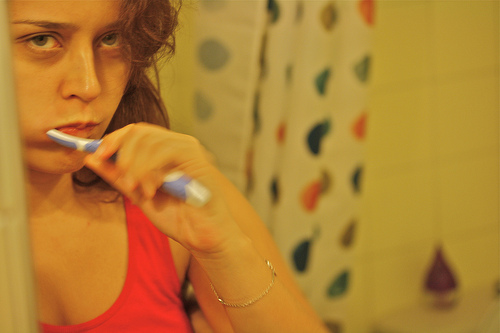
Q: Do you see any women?
A: Yes, there is a woman.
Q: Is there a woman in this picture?
A: Yes, there is a woman.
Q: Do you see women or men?
A: Yes, there is a woman.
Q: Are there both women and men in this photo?
A: No, there is a woman but no men.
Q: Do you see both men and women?
A: No, there is a woman but no men.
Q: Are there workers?
A: No, there are no workers.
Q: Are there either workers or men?
A: No, there are no workers or men.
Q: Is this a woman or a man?
A: This is a woman.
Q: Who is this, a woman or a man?
A: This is a woman.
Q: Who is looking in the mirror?
A: The woman is looking in the mirror.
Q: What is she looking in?
A: The woman is looking in the mirror.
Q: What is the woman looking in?
A: The woman is looking in the mirror.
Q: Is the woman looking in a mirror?
A: Yes, the woman is looking in a mirror.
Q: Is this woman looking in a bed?
A: No, the woman is looking in a mirror.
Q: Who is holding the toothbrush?
A: The woman is holding the toothbrush.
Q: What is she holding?
A: The woman is holding the toothbrush.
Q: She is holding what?
A: The woman is holding the toothbrush.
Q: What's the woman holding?
A: The woman is holding the toothbrush.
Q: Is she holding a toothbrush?
A: Yes, the woman is holding a toothbrush.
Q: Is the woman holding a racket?
A: No, the woman is holding a toothbrush.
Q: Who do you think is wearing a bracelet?
A: The woman is wearing a bracelet.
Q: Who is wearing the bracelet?
A: The woman is wearing a bracelet.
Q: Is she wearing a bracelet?
A: Yes, the woman is wearing a bracelet.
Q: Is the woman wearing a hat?
A: No, the woman is wearing a bracelet.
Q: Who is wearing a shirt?
A: The woman is wearing a shirt.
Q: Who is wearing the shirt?
A: The woman is wearing a shirt.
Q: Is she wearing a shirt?
A: Yes, the woman is wearing a shirt.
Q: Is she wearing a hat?
A: No, the woman is wearing a shirt.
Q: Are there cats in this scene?
A: No, there are no cats.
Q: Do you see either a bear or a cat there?
A: No, there are no cats or bears.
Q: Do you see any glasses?
A: No, there are no glasses.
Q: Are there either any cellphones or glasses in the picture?
A: No, there are no glasses or cellphones.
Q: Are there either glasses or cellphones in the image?
A: No, there are no glasses or cellphones.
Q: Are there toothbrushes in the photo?
A: Yes, there is a toothbrush.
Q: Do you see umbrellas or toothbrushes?
A: Yes, there is a toothbrush.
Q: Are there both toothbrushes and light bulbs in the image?
A: No, there is a toothbrush but no light bulbs.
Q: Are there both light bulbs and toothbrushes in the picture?
A: No, there is a toothbrush but no light bulbs.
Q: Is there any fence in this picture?
A: No, there are no fences.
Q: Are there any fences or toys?
A: No, there are no fences or toys.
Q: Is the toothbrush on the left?
A: Yes, the toothbrush is on the left of the image.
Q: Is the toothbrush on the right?
A: No, the toothbrush is on the left of the image.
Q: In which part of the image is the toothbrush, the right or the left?
A: The toothbrush is on the left of the image.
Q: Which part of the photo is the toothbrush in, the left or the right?
A: The toothbrush is on the left of the image.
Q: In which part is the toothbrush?
A: The toothbrush is on the left of the image.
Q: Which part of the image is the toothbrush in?
A: The toothbrush is on the left of the image.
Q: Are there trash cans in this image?
A: No, there are no trash cans.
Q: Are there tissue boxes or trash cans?
A: No, there are no trash cans or tissue boxes.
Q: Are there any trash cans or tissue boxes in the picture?
A: No, there are no trash cans or tissue boxes.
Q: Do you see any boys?
A: No, there are no boys.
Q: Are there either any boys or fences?
A: No, there are no boys or fences.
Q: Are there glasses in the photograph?
A: No, there are no glasses.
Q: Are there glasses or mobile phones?
A: No, there are no glasses or mobile phones.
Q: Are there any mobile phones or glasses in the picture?
A: No, there are no glasses or mobile phones.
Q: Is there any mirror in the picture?
A: Yes, there is a mirror.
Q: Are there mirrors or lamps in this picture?
A: Yes, there is a mirror.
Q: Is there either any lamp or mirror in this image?
A: Yes, there is a mirror.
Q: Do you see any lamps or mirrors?
A: Yes, there is a mirror.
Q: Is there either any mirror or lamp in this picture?
A: Yes, there is a mirror.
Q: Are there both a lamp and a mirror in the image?
A: No, there is a mirror but no lamps.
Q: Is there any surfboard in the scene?
A: No, there are no surfboards.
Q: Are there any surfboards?
A: No, there are no surfboards.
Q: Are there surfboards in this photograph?
A: No, there are no surfboards.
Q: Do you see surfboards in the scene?
A: No, there are no surfboards.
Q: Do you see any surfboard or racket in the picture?
A: No, there are no surfboards or rackets.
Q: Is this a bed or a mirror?
A: This is a mirror.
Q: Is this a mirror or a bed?
A: This is a mirror.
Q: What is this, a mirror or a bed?
A: This is a mirror.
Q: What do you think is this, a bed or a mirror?
A: This is a mirror.